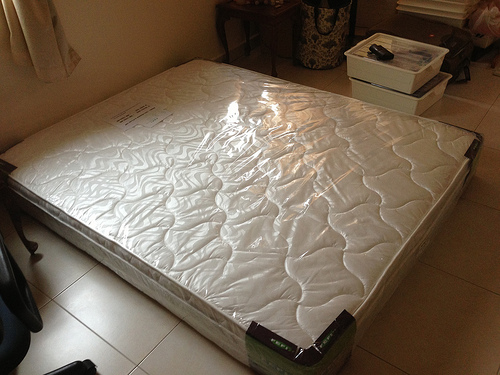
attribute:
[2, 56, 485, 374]
bed — new, white, large, rectangle, plastic colored, flat, comfy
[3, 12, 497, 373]
floor — white, tiled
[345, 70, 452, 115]
box — white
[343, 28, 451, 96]
box — white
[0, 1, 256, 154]
wall — brown, tan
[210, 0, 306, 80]
table — brown, small, dark colored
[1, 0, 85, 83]
drapery — hanging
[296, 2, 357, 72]
bag — colorful, designed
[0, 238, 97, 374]
chair — black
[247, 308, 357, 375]
edge protector — black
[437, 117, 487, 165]
edge protector — black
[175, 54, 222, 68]
edge protector — black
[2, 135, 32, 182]
edge protector — black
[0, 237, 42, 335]
chair arm — black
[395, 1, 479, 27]
tray — cream colored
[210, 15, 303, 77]
legs — wooden